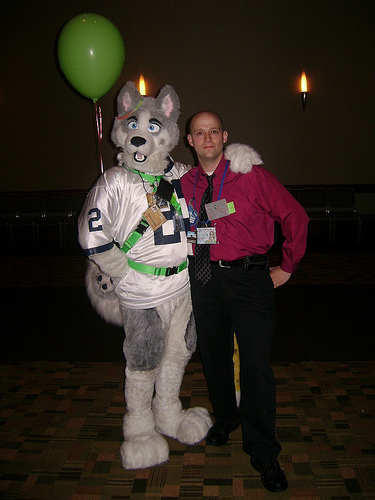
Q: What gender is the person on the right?
A: Male.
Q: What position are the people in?
A: Standing.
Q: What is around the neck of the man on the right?
A: Tie.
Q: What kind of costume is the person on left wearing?
A: Wolf.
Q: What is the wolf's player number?
A: Two.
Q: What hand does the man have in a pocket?
A: Left.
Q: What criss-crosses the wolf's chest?
A: Straps.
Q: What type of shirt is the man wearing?
A: Long-sleeved.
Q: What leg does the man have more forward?
A: Left.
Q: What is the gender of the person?
A: Male.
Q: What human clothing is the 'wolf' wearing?
A: Shirt.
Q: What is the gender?
A: Male.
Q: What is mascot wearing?
A: Jersey.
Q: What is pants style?
A: Black.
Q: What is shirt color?
A: Red.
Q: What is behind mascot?
A: Balloon.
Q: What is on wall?
A: Lights.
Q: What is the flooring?
A: Carpet.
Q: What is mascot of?
A: Wolf.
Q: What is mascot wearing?
A: Harness.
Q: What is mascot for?
A: Sports team.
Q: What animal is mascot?
A: Coyote.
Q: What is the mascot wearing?
A: Jersey.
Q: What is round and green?
A: Balloon.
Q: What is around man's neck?
A: Tie.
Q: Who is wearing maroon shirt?
A: The man.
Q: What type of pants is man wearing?
A: Black pants.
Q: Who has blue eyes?
A: Mascot.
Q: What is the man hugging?
A: A mascot.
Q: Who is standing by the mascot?
A: A man.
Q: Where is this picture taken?
A: At a conference.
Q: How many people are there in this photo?
A: Two.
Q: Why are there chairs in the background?
A: They are there for people to sit on.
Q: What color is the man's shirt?
A: Red.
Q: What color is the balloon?
A: Green.